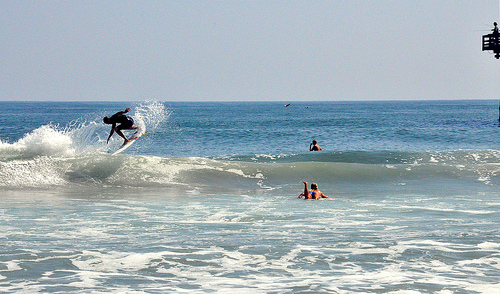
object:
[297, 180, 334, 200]
person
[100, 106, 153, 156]
motion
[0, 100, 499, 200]
wave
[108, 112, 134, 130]
outfit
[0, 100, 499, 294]
ocean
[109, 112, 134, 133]
wetsuit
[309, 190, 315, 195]
bikini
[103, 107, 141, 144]
man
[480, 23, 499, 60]
deck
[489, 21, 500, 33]
person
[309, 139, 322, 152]
man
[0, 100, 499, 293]
water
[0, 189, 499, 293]
waves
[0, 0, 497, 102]
sky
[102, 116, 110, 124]
head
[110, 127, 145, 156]
surfboard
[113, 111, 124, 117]
arm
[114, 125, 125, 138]
leg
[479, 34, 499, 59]
pier